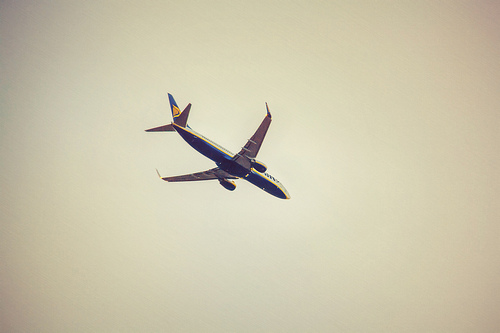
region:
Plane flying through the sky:
[145, 94, 291, 203]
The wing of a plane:
[234, 104, 274, 161]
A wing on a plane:
[158, 162, 233, 185]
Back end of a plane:
[144, 90, 215, 157]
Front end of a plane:
[254, 171, 292, 203]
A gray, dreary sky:
[3, 4, 489, 331]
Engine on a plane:
[251, 157, 269, 174]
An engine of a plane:
[217, 176, 236, 192]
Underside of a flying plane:
[144, 90, 291, 204]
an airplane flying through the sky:
[150, 90, 290, 202]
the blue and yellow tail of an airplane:
[146, 91, 194, 141]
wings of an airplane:
[165, 96, 292, 191]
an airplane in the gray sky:
[125, 80, 299, 212]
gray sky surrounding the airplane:
[2, 4, 499, 331]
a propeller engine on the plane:
[250, 158, 268, 178]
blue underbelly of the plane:
[168, 126, 293, 203]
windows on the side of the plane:
[256, 169, 288, 193]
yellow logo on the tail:
[171, 103, 183, 120]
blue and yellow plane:
[145, 91, 297, 209]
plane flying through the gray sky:
[143, 89, 299, 205]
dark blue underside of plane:
[181, 129, 283, 197]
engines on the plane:
[218, 158, 267, 196]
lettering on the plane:
[254, 165, 280, 184]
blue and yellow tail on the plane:
[165, 93, 182, 123]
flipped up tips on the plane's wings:
[154, 100, 281, 186]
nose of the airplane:
[281, 189, 289, 201]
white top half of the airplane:
[185, 127, 294, 204]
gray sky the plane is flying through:
[5, 3, 488, 331]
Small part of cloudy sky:
[5, 270, 61, 323]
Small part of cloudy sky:
[75, 277, 135, 314]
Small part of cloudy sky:
[224, 298, 265, 332]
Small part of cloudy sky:
[285, 291, 320, 327]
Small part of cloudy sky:
[318, 271, 340, 308]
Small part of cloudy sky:
[408, 257, 451, 308]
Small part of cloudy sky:
[380, 175, 426, 221]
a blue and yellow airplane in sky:
[145, 89, 287, 198]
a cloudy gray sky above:
[6, 5, 488, 325]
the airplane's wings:
[157, 104, 270, 184]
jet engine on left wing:
[216, 176, 236, 191]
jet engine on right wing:
[248, 155, 265, 172]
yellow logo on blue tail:
[171, 103, 179, 120]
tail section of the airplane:
[144, 91, 191, 133]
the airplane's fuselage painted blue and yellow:
[174, 124, 288, 201]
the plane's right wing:
[235, 101, 273, 168]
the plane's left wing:
[156, 162, 238, 190]